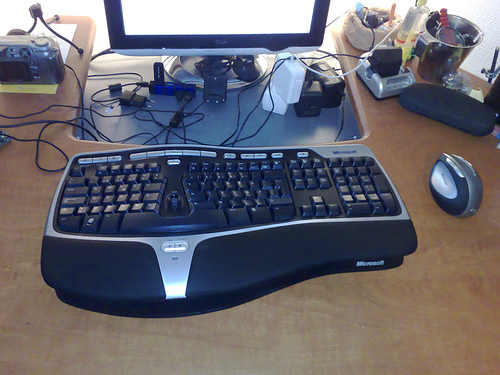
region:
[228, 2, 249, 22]
part of a screen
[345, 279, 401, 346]
part of a desktop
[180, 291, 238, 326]
edge of a keyboard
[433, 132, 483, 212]
part of a mouse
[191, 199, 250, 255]
part of some buttons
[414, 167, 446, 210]
edge of a mouse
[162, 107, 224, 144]
part of some wires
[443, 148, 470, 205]
part of a mouse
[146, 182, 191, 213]
part of some button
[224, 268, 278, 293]
edge of a keyboard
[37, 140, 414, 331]
A wireless gaming keyboard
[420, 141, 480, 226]
A wireless mouse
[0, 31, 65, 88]
Digital camera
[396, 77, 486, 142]
Case for eye glasses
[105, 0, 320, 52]
LCD computer monitor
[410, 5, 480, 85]
Cup holding office supplies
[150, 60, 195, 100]
Usb slots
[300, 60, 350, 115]
DC outlet not plugged in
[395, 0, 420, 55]
Ink for a printer in a case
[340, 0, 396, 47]
Ashtray on the back of the table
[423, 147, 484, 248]
the mouse is wireless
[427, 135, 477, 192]
the mouse is wirelessthe mouse is wireless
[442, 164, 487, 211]
the mouse is wireless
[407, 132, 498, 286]
the mouse is wireless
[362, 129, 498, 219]
an optical mouse on table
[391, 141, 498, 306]
an optical mouse on table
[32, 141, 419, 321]
Computer keyboard on a desk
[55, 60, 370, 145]
Electronics cables and power cords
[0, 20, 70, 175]
Digital camera and cables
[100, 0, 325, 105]
Computer monitor on a desk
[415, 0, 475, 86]
Metal cup full of trinkets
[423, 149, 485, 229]
Wireless computer mouse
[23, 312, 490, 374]
Wood computer desk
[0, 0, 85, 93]
Digital camera and small wire tripod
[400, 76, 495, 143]
Black case for glasses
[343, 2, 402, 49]
Small bowl with miscellaneous items